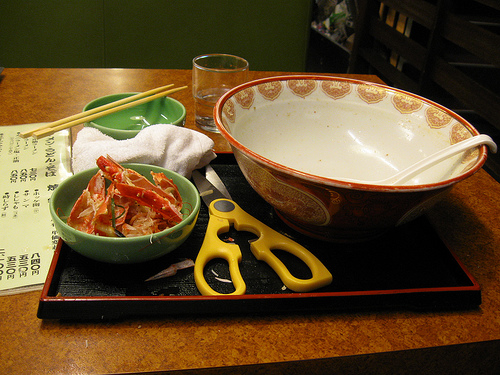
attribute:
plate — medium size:
[32, 147, 484, 320]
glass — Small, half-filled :
[189, 53, 248, 135]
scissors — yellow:
[192, 184, 347, 302]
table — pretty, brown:
[0, 62, 499, 369]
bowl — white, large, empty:
[215, 70, 498, 242]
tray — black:
[35, 150, 482, 320]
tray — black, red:
[68, 139, 480, 327]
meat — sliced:
[66, 151, 196, 244]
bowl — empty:
[195, 69, 495, 251]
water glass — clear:
[194, 55, 231, 138]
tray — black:
[31, 243, 478, 317]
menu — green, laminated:
[0, 122, 63, 296]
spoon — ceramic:
[387, 132, 496, 187]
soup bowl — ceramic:
[210, 70, 490, 246]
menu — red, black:
[1, 119, 73, 292]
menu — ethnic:
[0, 119, 80, 300]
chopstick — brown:
[13, 81, 176, 141]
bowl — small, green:
[84, 89, 189, 138]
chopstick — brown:
[32, 81, 188, 139]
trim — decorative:
[215, 71, 487, 191]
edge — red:
[39, 288, 353, 308]